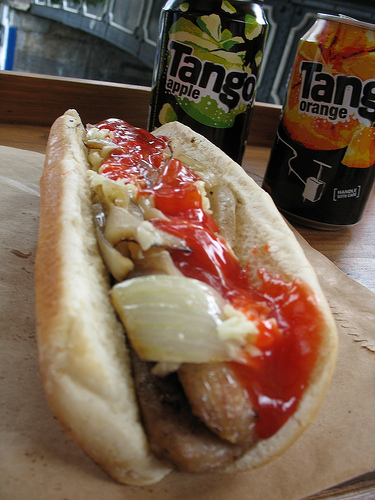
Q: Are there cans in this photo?
A: Yes, there is a can.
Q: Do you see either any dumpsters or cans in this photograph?
A: Yes, there is a can.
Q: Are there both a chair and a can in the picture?
A: No, there is a can but no chairs.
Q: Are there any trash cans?
A: No, there are no trash cans.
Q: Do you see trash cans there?
A: No, there are no trash cans.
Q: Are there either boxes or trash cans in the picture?
A: No, there are no trash cans or boxes.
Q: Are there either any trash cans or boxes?
A: No, there are no trash cans or boxes.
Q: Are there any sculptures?
A: No, there are no sculptures.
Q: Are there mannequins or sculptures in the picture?
A: No, there are no sculptures or mannequins.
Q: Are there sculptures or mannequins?
A: No, there are no sculptures or mannequins.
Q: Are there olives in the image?
A: No, there are no olives.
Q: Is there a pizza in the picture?
A: No, there are no pizzas.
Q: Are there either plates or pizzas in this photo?
A: No, there are no pizzas or plates.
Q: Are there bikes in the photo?
A: No, there are no bikes.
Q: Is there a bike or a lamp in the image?
A: No, there are no bikes or lamps.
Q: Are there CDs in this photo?
A: No, there are no cds.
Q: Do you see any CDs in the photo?
A: No, there are no cds.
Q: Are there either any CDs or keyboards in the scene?
A: No, there are no CDs or keyboards.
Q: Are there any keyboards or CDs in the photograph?
A: No, there are no CDs or keyboards.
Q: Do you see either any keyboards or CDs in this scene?
A: No, there are no CDs or keyboards.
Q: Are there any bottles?
A: No, there are no bottles.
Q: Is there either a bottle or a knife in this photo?
A: No, there are no bottles or knives.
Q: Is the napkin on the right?
A: Yes, the napkin is on the right of the image.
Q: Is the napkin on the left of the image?
A: No, the napkin is on the right of the image.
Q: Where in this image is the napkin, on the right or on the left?
A: The napkin is on the right of the image.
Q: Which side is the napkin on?
A: The napkin is on the right of the image.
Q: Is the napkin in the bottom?
A: Yes, the napkin is in the bottom of the image.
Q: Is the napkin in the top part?
A: No, the napkin is in the bottom of the image.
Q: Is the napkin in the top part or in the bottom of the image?
A: The napkin is in the bottom of the image.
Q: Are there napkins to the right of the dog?
A: Yes, there is a napkin to the right of the dog.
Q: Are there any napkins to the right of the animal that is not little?
A: Yes, there is a napkin to the right of the dog.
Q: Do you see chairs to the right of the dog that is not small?
A: No, there is a napkin to the right of the dog.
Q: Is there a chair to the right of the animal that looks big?
A: No, there is a napkin to the right of the dog.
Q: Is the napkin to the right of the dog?
A: Yes, the napkin is to the right of the dog.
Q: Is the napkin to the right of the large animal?
A: Yes, the napkin is to the right of the dog.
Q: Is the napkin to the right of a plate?
A: No, the napkin is to the right of the dog.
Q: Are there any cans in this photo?
A: Yes, there is a can.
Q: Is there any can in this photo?
A: Yes, there is a can.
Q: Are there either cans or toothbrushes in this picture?
A: Yes, there is a can.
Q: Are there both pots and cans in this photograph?
A: No, there is a can but no pots.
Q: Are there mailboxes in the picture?
A: No, there are no mailboxes.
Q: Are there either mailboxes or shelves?
A: No, there are no mailboxes or shelves.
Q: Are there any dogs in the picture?
A: Yes, there is a dog.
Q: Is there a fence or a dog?
A: Yes, there is a dog.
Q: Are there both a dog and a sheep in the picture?
A: No, there is a dog but no sheep.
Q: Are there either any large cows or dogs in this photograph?
A: Yes, there is a large dog.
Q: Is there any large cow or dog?
A: Yes, there is a large dog.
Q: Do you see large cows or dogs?
A: Yes, there is a large dog.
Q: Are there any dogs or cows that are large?
A: Yes, the dog is large.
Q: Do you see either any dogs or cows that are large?
A: Yes, the dog is large.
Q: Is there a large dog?
A: Yes, there is a large dog.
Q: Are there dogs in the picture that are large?
A: Yes, there is a dog that is large.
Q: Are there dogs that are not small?
A: Yes, there is a large dog.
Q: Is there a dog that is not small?
A: Yes, there is a large dog.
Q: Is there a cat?
A: No, there are no cats.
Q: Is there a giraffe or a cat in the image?
A: No, there are no cats or giraffes.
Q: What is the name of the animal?
A: The animal is a dog.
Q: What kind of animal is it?
A: The animal is a dog.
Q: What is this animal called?
A: This is a dog.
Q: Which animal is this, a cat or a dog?
A: This is a dog.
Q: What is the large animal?
A: The animal is a dog.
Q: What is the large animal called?
A: The animal is a dog.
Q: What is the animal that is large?
A: The animal is a dog.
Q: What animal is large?
A: The animal is a dog.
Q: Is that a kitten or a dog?
A: That is a dog.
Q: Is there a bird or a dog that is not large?
A: No, there is a dog but it is large.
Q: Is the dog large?
A: Yes, the dog is large.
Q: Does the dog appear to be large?
A: Yes, the dog is large.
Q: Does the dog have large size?
A: Yes, the dog is large.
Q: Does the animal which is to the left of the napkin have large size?
A: Yes, the dog is large.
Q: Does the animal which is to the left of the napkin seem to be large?
A: Yes, the dog is large.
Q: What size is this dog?
A: The dog is large.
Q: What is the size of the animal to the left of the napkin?
A: The dog is large.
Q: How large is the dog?
A: The dog is large.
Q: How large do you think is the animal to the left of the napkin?
A: The dog is large.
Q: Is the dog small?
A: No, the dog is large.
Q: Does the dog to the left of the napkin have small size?
A: No, the dog is large.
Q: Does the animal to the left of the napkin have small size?
A: No, the dog is large.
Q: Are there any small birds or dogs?
A: No, there is a dog but it is large.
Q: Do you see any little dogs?
A: No, there is a dog but it is large.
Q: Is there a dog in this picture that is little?
A: No, there is a dog but it is large.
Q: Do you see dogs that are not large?
A: No, there is a dog but it is large.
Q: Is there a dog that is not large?
A: No, there is a dog but it is large.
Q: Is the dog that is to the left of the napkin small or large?
A: The dog is large.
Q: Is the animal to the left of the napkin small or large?
A: The dog is large.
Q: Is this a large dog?
A: Yes, this is a large dog.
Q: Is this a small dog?
A: No, this is a large dog.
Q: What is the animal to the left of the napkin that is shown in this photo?
A: The animal is a dog.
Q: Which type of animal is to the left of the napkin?
A: The animal is a dog.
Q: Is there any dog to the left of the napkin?
A: Yes, there is a dog to the left of the napkin.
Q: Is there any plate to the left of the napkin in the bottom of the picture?
A: No, there is a dog to the left of the napkin.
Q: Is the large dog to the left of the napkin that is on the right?
A: Yes, the dog is to the left of the napkin.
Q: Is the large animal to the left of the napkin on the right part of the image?
A: Yes, the dog is to the left of the napkin.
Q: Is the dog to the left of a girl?
A: No, the dog is to the left of the napkin.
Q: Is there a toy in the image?
A: No, there are no toys.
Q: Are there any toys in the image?
A: No, there are no toys.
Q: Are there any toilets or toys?
A: No, there are no toys or toilets.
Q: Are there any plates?
A: No, there are no plates.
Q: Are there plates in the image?
A: No, there are no plates.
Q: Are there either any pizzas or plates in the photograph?
A: No, there are no plates or pizzas.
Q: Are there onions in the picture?
A: Yes, there is an onion.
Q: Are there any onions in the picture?
A: Yes, there is an onion.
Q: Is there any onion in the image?
A: Yes, there is an onion.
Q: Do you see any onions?
A: Yes, there is an onion.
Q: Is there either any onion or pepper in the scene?
A: Yes, there is an onion.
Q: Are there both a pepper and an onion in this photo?
A: No, there is an onion but no peppers.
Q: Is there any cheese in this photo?
A: No, there is no cheese.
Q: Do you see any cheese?
A: No, there is no cheese.